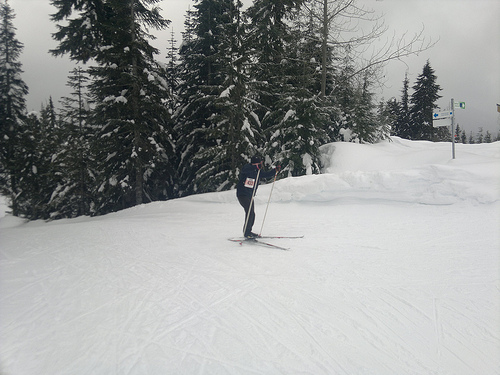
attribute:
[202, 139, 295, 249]
man — skiing, here, present, wearing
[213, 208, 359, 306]
skis — crossed, started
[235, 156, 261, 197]
person — skiing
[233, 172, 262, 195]
bib — numbered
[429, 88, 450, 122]
sign — white, green, blue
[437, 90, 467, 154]
pole — holding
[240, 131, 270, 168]
beanie — black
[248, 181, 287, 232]
poles — paired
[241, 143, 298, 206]
skier — pictured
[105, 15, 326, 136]
trees — covered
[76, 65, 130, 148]
leaves — covered